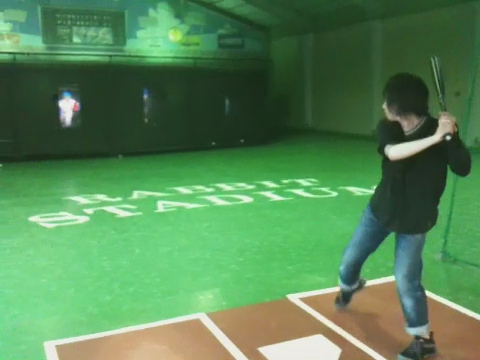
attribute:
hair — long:
[383, 71, 431, 122]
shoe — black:
[335, 275, 365, 309]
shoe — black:
[395, 327, 436, 358]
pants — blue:
[336, 205, 432, 336]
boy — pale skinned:
[333, 72, 470, 358]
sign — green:
[36, 6, 128, 50]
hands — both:
[432, 111, 464, 141]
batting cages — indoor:
[440, 63, 480, 268]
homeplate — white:
[250, 327, 347, 359]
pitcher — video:
[51, 86, 92, 132]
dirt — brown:
[296, 276, 480, 357]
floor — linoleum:
[3, 157, 473, 323]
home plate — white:
[250, 328, 345, 358]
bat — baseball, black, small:
[431, 54, 458, 142]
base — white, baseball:
[252, 330, 348, 359]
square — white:
[294, 271, 480, 356]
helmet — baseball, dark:
[63, 89, 77, 99]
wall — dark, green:
[271, 32, 479, 146]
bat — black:
[411, 43, 459, 153]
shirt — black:
[355, 114, 443, 238]